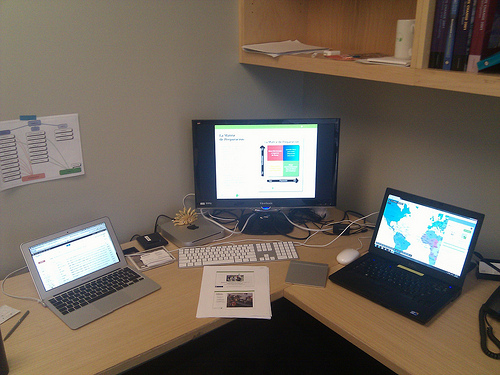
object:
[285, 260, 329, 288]
pad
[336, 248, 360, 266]
mouse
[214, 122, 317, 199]
monitor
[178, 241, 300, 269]
keyboard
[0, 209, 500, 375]
wooden desktop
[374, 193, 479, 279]
monitor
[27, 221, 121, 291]
monitor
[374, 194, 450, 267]
map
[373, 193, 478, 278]
screen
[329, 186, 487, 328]
laptop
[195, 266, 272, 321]
papers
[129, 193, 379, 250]
wires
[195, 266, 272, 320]
paper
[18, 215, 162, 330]
laptop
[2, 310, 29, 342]
pen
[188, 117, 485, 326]
computers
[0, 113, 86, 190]
chart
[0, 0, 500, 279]
wall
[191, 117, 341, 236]
computer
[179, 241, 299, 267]
keys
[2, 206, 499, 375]
desk